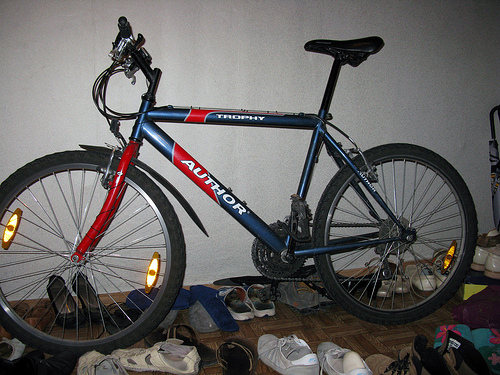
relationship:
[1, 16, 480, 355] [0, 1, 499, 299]
bicycle against wall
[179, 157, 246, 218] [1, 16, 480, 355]
lettering on bicycle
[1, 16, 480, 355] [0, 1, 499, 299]
bicycle leaning against wall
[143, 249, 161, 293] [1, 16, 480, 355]
reflector on bicycle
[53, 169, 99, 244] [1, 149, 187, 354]
spokes on wheel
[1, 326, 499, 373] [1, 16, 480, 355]
shoes in front of bicycle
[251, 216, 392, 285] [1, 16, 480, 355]
chain on bicycle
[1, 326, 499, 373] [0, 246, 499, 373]
shoes on floor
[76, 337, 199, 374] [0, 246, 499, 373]
shoes on floor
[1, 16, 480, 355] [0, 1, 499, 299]
bicycle leaning on wall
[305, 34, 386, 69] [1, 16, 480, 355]
seat on bicycle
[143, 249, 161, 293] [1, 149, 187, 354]
reflector on wheel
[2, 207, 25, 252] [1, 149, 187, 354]
reflector on wheel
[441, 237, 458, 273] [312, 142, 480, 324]
reflector on wheel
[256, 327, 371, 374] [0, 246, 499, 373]
shoes on floor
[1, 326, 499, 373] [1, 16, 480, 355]
shoes around bicycle